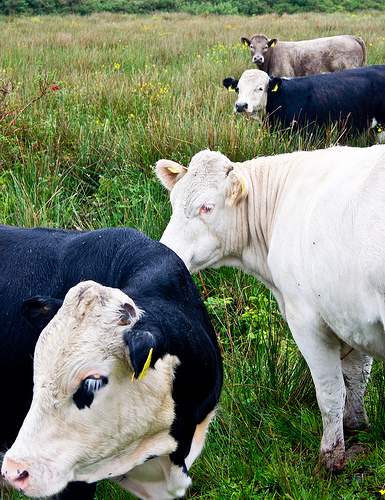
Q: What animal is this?
A: Cow.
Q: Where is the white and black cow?
A: In a field.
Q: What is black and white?
A: The cow.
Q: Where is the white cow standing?
A: On grass.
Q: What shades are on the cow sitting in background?
A: Black and white.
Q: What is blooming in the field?
A: Yellow flowers.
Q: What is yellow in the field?
A: Small cluster of flowers.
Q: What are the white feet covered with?
A: Mud.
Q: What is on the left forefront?
A: Black cow with a white head.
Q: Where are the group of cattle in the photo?
A: In the tall green grass.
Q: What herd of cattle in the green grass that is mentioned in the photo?
A: White, black and brown cattle.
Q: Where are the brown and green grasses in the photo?
A: Around the cows.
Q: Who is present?
A: Nobody.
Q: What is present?
A: Animals.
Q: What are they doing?
A: Grazing.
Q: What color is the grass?
A: Green.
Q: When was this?
A: Daytime.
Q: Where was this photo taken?
A: In a pasture.